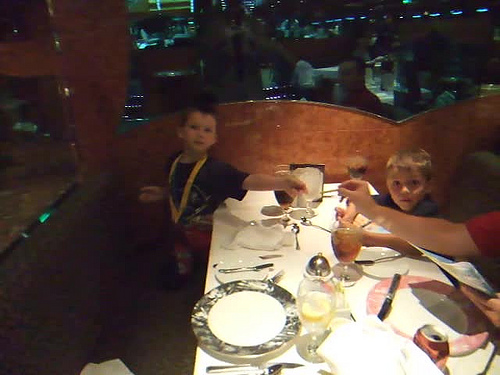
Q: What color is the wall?
A: Brown.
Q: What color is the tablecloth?
A: White.